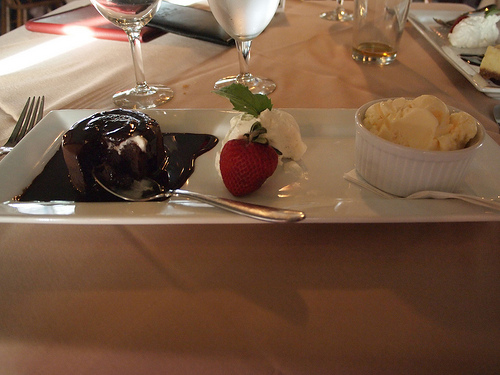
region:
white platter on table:
[7, 77, 498, 253]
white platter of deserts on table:
[0, 94, 499, 254]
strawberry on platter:
[192, 87, 317, 203]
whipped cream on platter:
[205, 80, 327, 194]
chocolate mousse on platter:
[10, 90, 227, 249]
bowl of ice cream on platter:
[334, 80, 488, 231]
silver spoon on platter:
[87, 154, 324, 276]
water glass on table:
[197, 0, 294, 110]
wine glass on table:
[85, 2, 202, 123]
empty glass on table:
[343, 0, 428, 80]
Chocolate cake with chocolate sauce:
[48, 95, 243, 275]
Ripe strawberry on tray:
[188, 88, 295, 217]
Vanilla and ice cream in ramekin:
[364, 72, 473, 256]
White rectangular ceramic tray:
[24, 90, 488, 254]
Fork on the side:
[8, 88, 75, 182]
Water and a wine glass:
[102, 2, 272, 134]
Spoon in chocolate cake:
[104, 144, 334, 289]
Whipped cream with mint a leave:
[235, 88, 297, 154]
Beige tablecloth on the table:
[35, 198, 400, 373]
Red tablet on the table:
[25, 2, 193, 72]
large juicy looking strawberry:
[219, 122, 278, 194]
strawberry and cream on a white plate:
[211, 109, 307, 200]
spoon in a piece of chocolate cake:
[88, 163, 305, 223]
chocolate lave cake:
[18, 106, 218, 208]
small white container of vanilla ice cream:
[346, 93, 488, 195]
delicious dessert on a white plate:
[0, 93, 499, 223]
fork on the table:
[1, 91, 52, 158]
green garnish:
[213, 81, 274, 116]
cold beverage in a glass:
[205, 0, 282, 99]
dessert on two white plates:
[1, 5, 495, 239]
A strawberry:
[211, 130, 298, 201]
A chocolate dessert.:
[55, 97, 196, 199]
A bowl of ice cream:
[343, 89, 486, 203]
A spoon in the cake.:
[88, 158, 308, 237]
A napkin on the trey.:
[336, 162, 498, 208]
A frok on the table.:
[1, 86, 45, 154]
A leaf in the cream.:
[211, 75, 276, 121]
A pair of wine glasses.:
[86, 1, 301, 108]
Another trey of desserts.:
[419, 1, 499, 99]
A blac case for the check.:
[138, 0, 233, 47]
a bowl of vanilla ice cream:
[336, 82, 479, 178]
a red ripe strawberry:
[206, 113, 293, 205]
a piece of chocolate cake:
[45, 91, 182, 193]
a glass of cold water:
[195, 0, 280, 101]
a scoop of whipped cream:
[186, 69, 308, 167]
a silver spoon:
[76, 160, 313, 239]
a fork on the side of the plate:
[5, 85, 54, 228]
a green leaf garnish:
[207, 70, 274, 125]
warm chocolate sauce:
[139, 113, 208, 185]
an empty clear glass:
[321, 0, 417, 73]